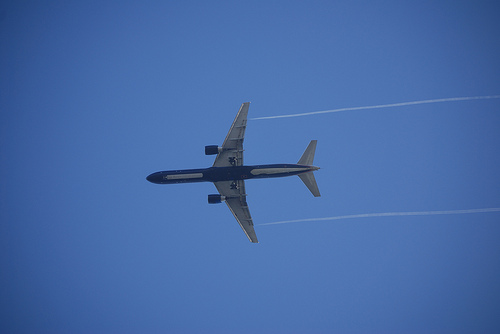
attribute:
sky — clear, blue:
[17, 7, 489, 319]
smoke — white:
[239, 71, 498, 238]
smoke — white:
[244, 92, 495, 126]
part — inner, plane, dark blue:
[142, 160, 320, 185]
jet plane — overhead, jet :
[145, 102, 322, 242]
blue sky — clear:
[0, 0, 497, 105]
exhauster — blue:
[199, 140, 226, 157]